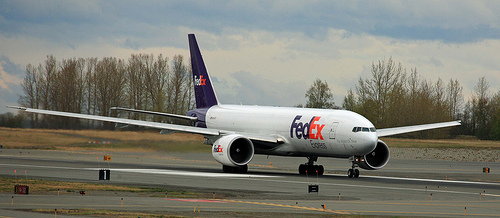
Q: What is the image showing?
A: It is showing a road.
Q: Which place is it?
A: It is a road.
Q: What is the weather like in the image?
A: It is cloudy.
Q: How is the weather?
A: It is cloudy.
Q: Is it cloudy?
A: Yes, it is cloudy.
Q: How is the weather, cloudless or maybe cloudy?
A: It is cloudy.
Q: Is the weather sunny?
A: No, it is cloudy.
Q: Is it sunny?
A: No, it is cloudy.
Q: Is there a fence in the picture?
A: No, there are no fences.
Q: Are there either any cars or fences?
A: No, there are no fences or cars.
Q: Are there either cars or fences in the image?
A: No, there are no fences or cars.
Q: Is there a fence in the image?
A: No, there are no fences.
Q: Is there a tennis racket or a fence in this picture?
A: No, there are no fences or rackets.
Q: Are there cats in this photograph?
A: No, there are no cats.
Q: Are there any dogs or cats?
A: No, there are no cats or dogs.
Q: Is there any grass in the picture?
A: Yes, there is grass.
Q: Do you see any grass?
A: Yes, there is grass.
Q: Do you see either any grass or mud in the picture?
A: Yes, there is grass.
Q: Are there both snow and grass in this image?
A: No, there is grass but no snow.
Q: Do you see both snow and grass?
A: No, there is grass but no snow.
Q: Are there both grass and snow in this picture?
A: No, there is grass but no snow.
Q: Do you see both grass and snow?
A: No, there is grass but no snow.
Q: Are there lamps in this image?
A: No, there are no lamps.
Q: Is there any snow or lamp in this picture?
A: No, there are no lamps or snow.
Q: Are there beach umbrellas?
A: No, there are no beach umbrellas.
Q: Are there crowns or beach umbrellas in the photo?
A: No, there are no beach umbrellas or crowns.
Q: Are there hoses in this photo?
A: No, there are no hoses.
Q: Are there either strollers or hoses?
A: No, there are no hoses or strollers.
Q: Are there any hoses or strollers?
A: No, there are no hoses or strollers.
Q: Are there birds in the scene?
A: No, there are no birds.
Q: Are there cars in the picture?
A: No, there are no cars.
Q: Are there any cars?
A: No, there are no cars.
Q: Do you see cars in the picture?
A: No, there are no cars.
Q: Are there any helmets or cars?
A: No, there are no cars or helmets.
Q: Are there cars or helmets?
A: No, there are no cars or helmets.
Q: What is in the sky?
A: The clouds are in the sky.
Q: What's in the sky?
A: The clouds are in the sky.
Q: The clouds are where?
A: The clouds are in the sky.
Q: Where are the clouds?
A: The clouds are in the sky.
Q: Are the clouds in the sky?
A: Yes, the clouds are in the sky.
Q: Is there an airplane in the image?
A: Yes, there is an airplane.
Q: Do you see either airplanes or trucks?
A: Yes, there is an airplane.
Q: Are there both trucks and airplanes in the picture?
A: No, there is an airplane but no trucks.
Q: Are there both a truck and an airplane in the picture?
A: No, there is an airplane but no trucks.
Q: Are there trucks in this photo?
A: No, there are no trucks.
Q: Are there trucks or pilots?
A: No, there are no trucks or pilots.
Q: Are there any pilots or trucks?
A: No, there are no trucks or pilots.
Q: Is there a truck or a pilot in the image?
A: No, there are no trucks or pilots.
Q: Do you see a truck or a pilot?
A: No, there are no trucks or pilots.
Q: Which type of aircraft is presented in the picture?
A: The aircraft is an airplane.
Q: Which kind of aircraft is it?
A: The aircraft is an airplane.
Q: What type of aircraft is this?
A: This is an airplane.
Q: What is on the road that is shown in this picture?
A: The plane is on the road.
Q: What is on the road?
A: The plane is on the road.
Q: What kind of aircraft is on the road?
A: The aircraft is an airplane.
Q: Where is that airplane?
A: The airplane is on the road.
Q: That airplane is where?
A: The airplane is on the road.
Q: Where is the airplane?
A: The airplane is on the road.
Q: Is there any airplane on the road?
A: Yes, there is an airplane on the road.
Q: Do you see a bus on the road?
A: No, there is an airplane on the road.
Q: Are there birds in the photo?
A: No, there are no birds.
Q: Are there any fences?
A: No, there are no fences.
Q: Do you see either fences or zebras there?
A: No, there are no fences or zebras.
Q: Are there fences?
A: No, there are no fences.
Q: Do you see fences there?
A: No, there are no fences.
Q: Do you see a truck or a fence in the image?
A: No, there are no fences or trucks.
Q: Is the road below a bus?
A: No, the road is below the plane.